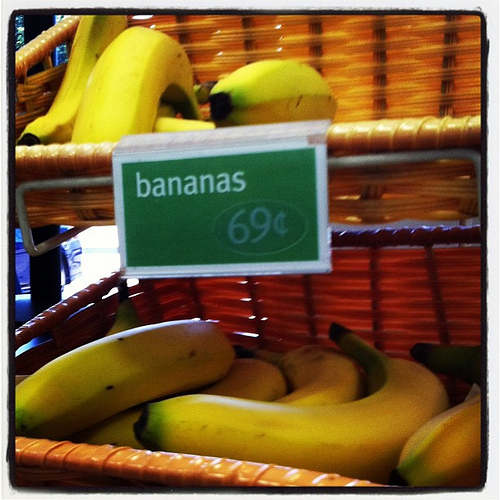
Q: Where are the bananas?
A: In a basket.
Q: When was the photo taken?
A: While at the store.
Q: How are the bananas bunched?
A: Individually.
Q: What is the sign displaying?
A: Sales price.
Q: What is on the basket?
A: A sign.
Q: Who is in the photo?
A: No one.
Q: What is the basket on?
A: A shelf.